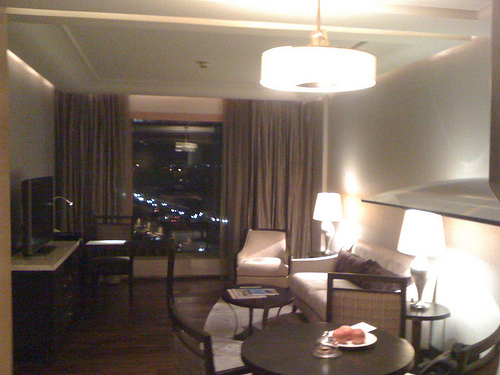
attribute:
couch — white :
[285, 228, 447, 326]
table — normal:
[200, 275, 293, 327]